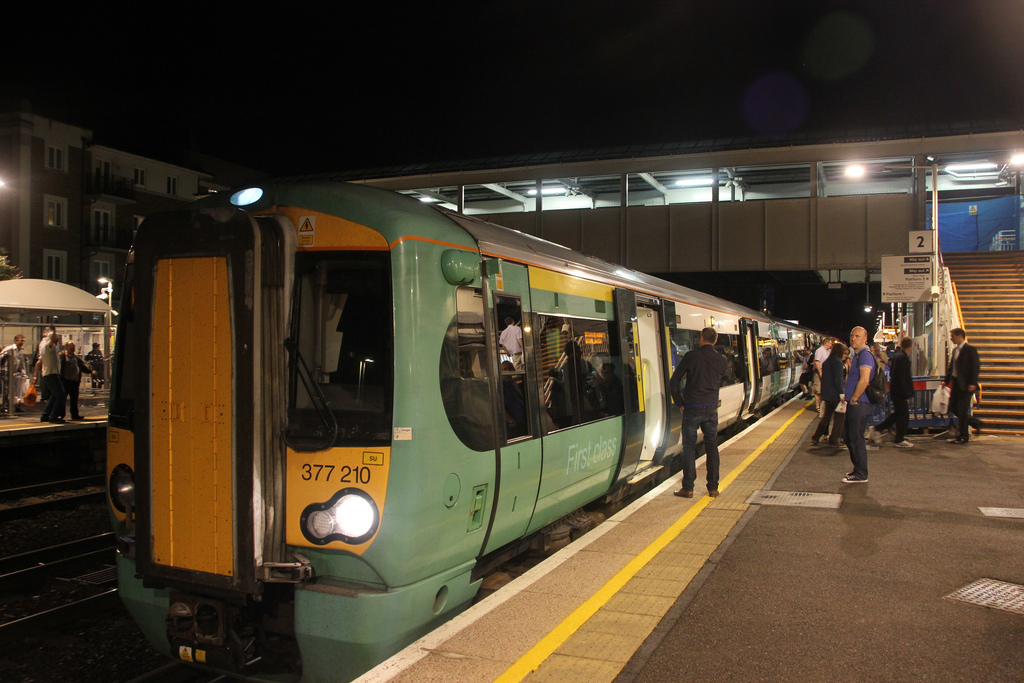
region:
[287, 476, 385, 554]
a headlight is lit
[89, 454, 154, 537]
a headlight is unlit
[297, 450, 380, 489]
the numbers are black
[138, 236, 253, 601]
the door is yellow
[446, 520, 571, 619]
the line is yellow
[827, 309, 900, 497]
man carrying a backpack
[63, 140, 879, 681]
train stopped next a platform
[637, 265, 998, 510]
people on a train station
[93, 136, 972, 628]
The train is green and yellow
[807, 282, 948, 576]
A man in a blue shirt is standing on the train platform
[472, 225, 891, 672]
A yellow line is on the train platform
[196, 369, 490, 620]
The train has a headlight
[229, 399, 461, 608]
Numbers on the front of the train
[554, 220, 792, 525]
The train doors are open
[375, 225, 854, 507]
The train windows are black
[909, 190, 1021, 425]
A blue wall is above the stairs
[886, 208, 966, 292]
A white sign has the number 2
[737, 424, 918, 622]
A square on the ground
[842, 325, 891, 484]
Man in blue t-shirt with a backpack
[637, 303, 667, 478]
Doors to the subway car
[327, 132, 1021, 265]
Walkway over the subway tracks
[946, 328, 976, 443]
Man in a black business suit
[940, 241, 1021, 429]
Stairway is painted with a yellow stripe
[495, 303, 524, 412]
Man in a white shirt's reflection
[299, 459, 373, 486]
Black numbers of the subway car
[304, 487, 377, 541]
Light of the subway car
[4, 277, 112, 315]
White canopy as a shelter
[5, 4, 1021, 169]
Black night sky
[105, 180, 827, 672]
the green train on the tracks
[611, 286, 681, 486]
the open door on the train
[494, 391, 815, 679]
the yellow line on the train platform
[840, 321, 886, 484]
the man on the train platform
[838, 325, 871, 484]
the man is bald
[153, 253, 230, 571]
the yellow door on the back of the train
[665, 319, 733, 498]
the man standing by the open door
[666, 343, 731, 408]
the black leather jacket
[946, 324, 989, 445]
the man in the suit by the stairs